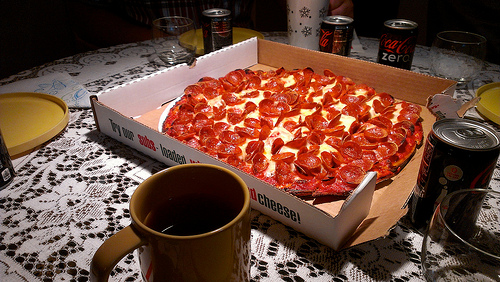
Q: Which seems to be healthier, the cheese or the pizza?
A: The cheese is healthier than the pizza.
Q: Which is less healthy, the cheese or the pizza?
A: The pizza is less healthy than the cheese.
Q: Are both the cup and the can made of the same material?
A: No, the cup is made of plastic and the can is made of metal.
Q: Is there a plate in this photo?
A: Yes, there is a plate.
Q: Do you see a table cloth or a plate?
A: Yes, there is a plate.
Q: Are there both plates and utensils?
A: No, there is a plate but no utensils.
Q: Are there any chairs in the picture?
A: No, there are no chairs.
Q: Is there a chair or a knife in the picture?
A: No, there are no chairs or knives.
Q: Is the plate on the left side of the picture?
A: Yes, the plate is on the left of the image.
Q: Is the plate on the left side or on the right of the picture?
A: The plate is on the left of the image.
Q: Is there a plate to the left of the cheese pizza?
A: Yes, there is a plate to the left of the pizza.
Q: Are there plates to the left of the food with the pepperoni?
A: Yes, there is a plate to the left of the pizza.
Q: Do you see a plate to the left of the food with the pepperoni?
A: Yes, there is a plate to the left of the pizza.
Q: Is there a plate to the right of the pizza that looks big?
A: No, the plate is to the left of the pizza.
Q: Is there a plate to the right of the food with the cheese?
A: No, the plate is to the left of the pizza.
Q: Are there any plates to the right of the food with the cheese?
A: No, the plate is to the left of the pizza.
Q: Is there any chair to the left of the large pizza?
A: No, there is a plate to the left of the pizza.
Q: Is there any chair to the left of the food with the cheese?
A: No, there is a plate to the left of the pizza.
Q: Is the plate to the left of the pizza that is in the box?
A: Yes, the plate is to the left of the pizza.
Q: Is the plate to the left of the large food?
A: Yes, the plate is to the left of the pizza.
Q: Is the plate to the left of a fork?
A: No, the plate is to the left of the pizza.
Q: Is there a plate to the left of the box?
A: Yes, there is a plate to the left of the box.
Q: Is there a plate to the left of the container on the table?
A: Yes, there is a plate to the left of the box.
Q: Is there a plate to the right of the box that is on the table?
A: No, the plate is to the left of the box.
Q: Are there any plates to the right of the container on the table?
A: No, the plate is to the left of the box.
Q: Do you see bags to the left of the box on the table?
A: No, there is a plate to the left of the box.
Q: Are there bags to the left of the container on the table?
A: No, there is a plate to the left of the box.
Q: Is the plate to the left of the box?
A: Yes, the plate is to the left of the box.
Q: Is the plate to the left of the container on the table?
A: Yes, the plate is to the left of the box.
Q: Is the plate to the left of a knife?
A: No, the plate is to the left of the box.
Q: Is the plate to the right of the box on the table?
A: No, the plate is to the left of the box.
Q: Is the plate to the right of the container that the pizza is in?
A: No, the plate is to the left of the box.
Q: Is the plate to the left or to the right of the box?
A: The plate is to the left of the box.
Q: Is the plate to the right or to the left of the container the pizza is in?
A: The plate is to the left of the box.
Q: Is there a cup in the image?
A: Yes, there is a cup.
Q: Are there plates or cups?
A: Yes, there is a cup.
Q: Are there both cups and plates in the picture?
A: Yes, there are both a cup and a plate.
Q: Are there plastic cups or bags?
A: Yes, there is a plastic cup.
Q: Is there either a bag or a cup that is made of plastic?
A: Yes, the cup is made of plastic.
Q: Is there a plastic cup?
A: Yes, there is a cup that is made of plastic.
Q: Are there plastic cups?
A: Yes, there is a cup that is made of plastic.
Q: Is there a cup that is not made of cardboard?
A: Yes, there is a cup that is made of plastic.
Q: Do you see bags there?
A: No, there are no bags.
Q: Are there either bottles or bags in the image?
A: No, there are no bags or bottles.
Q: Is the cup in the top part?
A: Yes, the cup is in the top of the image.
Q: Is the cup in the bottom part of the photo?
A: No, the cup is in the top of the image.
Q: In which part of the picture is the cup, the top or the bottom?
A: The cup is in the top of the image.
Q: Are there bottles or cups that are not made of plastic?
A: No, there is a cup but it is made of plastic.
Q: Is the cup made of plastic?
A: Yes, the cup is made of plastic.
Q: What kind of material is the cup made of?
A: The cup is made of plastic.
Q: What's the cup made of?
A: The cup is made of plastic.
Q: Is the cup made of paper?
A: No, the cup is made of plastic.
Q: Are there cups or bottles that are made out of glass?
A: No, there is a cup but it is made of plastic.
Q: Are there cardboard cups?
A: No, there is a cup but it is made of plastic.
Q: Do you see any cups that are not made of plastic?
A: No, there is a cup but it is made of plastic.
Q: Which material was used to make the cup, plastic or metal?
A: The cup is made of plastic.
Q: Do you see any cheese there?
A: Yes, there is cheese.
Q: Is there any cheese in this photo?
A: Yes, there is cheese.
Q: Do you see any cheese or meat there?
A: Yes, there is cheese.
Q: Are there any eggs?
A: No, there are no eggs.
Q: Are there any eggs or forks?
A: No, there are no eggs or forks.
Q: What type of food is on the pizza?
A: The food is cheese.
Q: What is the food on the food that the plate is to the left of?
A: The food is cheese.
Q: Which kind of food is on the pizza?
A: The food is cheese.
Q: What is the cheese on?
A: The cheese is on the pizza.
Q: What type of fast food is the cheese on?
A: The cheese is on the pizza.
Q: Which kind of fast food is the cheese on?
A: The cheese is on the pizza.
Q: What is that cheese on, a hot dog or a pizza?
A: The cheese is on a pizza.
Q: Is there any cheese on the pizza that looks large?
A: Yes, there is cheese on the pizza.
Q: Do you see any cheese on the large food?
A: Yes, there is cheese on the pizza.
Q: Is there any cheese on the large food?
A: Yes, there is cheese on the pizza.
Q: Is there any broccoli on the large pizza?
A: No, there is cheese on the pizza.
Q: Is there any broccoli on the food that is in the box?
A: No, there is cheese on the pizza.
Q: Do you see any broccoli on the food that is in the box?
A: No, there is cheese on the pizza.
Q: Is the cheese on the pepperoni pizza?
A: Yes, the cheese is on the pizza.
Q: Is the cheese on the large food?
A: Yes, the cheese is on the pizza.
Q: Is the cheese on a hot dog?
A: No, the cheese is on the pizza.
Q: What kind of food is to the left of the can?
A: The food is cheese.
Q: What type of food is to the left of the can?
A: The food is cheese.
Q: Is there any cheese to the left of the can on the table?
A: Yes, there is cheese to the left of the can.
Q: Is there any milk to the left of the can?
A: No, there is cheese to the left of the can.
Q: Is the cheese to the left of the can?
A: Yes, the cheese is to the left of the can.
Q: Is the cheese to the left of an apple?
A: No, the cheese is to the left of the can.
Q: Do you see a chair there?
A: No, there are no chairs.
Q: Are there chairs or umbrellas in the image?
A: No, there are no chairs or umbrellas.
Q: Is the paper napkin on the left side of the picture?
A: Yes, the napkin is on the left of the image.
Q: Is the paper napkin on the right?
A: No, the napkin is on the left of the image.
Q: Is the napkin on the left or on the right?
A: The napkin is on the left of the image.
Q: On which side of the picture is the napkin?
A: The napkin is on the left of the image.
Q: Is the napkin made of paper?
A: Yes, the napkin is made of paper.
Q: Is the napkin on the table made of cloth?
A: No, the napkin is made of paper.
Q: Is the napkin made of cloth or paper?
A: The napkin is made of paper.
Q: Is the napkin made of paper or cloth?
A: The napkin is made of paper.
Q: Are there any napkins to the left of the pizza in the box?
A: Yes, there is a napkin to the left of the pizza.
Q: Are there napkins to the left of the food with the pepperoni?
A: Yes, there is a napkin to the left of the pizza.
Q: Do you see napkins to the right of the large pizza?
A: No, the napkin is to the left of the pizza.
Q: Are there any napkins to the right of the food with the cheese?
A: No, the napkin is to the left of the pizza.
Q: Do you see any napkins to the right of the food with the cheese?
A: No, the napkin is to the left of the pizza.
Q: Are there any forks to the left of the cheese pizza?
A: No, there is a napkin to the left of the pizza.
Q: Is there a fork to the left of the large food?
A: No, there is a napkin to the left of the pizza.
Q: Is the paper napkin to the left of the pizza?
A: Yes, the napkin is to the left of the pizza.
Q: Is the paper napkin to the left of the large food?
A: Yes, the napkin is to the left of the pizza.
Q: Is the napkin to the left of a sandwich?
A: No, the napkin is to the left of the pizza.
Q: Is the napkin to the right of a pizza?
A: No, the napkin is to the left of a pizza.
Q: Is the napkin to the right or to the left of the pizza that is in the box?
A: The napkin is to the left of the pizza.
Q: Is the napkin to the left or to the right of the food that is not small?
A: The napkin is to the left of the pizza.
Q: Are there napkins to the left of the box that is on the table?
A: Yes, there is a napkin to the left of the box.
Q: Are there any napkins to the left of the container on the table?
A: Yes, there is a napkin to the left of the box.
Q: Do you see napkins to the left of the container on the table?
A: Yes, there is a napkin to the left of the box.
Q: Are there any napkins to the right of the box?
A: No, the napkin is to the left of the box.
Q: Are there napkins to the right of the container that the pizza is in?
A: No, the napkin is to the left of the box.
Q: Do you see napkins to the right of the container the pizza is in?
A: No, the napkin is to the left of the box.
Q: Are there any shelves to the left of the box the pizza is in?
A: No, there is a napkin to the left of the box.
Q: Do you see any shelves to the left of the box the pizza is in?
A: No, there is a napkin to the left of the box.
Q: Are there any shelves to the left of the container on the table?
A: No, there is a napkin to the left of the box.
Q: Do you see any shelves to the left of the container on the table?
A: No, there is a napkin to the left of the box.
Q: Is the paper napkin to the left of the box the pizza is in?
A: Yes, the napkin is to the left of the box.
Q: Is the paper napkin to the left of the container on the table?
A: Yes, the napkin is to the left of the box.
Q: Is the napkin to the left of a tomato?
A: No, the napkin is to the left of the box.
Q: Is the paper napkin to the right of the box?
A: No, the napkin is to the left of the box.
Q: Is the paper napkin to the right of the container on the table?
A: No, the napkin is to the left of the box.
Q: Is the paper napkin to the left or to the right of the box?
A: The napkin is to the left of the box.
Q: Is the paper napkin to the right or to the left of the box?
A: The napkin is to the left of the box.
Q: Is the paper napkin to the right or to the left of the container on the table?
A: The napkin is to the left of the box.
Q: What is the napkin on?
A: The napkin is on the table.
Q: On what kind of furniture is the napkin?
A: The napkin is on the table.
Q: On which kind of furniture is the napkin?
A: The napkin is on the table.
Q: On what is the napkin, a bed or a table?
A: The napkin is on a table.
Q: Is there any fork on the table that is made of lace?
A: No, there is a napkin on the table.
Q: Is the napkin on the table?
A: Yes, the napkin is on the table.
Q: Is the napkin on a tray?
A: No, the napkin is on the table.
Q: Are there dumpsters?
A: No, there are no dumpsters.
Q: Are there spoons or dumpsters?
A: No, there are no dumpsters or spoons.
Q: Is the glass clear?
A: Yes, the glass is clear.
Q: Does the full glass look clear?
A: Yes, the glass is clear.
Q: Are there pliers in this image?
A: No, there are no pliers.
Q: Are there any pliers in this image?
A: No, there are no pliers.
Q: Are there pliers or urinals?
A: No, there are no pliers or urinals.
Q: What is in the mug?
A: The liquid is in the mug.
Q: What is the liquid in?
A: The liquid is in the mug.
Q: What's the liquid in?
A: The liquid is in the mug.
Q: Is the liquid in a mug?
A: Yes, the liquid is in a mug.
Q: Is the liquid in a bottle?
A: No, the liquid is in a mug.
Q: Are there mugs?
A: Yes, there is a mug.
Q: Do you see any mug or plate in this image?
A: Yes, there is a mug.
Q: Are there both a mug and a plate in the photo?
A: Yes, there are both a mug and a plate.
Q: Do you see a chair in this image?
A: No, there are no chairs.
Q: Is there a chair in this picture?
A: No, there are no chairs.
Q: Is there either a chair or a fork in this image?
A: No, there are no chairs or forks.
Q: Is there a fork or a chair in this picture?
A: No, there are no chairs or forks.